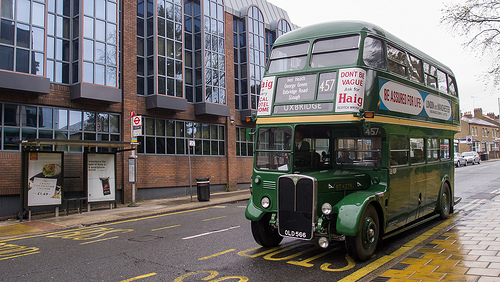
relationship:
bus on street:
[244, 20, 463, 263] [1, 160, 499, 282]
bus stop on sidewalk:
[18, 136, 142, 224] [0, 186, 253, 241]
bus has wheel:
[244, 20, 463, 263] [346, 205, 381, 262]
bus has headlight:
[244, 20, 463, 263] [321, 202, 331, 216]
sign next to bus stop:
[130, 113, 143, 138] [18, 136, 142, 224]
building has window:
[0, 0, 304, 214] [81, 60, 94, 82]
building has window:
[0, 0, 304, 214] [93, 61, 106, 86]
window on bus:
[311, 34, 361, 53] [244, 20, 463, 263]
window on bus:
[310, 50, 358, 68] [244, 20, 463, 263]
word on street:
[237, 240, 377, 272] [1, 160, 499, 282]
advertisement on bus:
[334, 67, 368, 114] [244, 20, 463, 263]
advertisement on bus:
[377, 74, 456, 124] [244, 20, 463, 263]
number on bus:
[318, 79, 336, 92] [244, 20, 463, 263]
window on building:
[81, 60, 94, 82] [0, 0, 304, 214]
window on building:
[93, 61, 106, 86] [0, 0, 304, 214]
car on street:
[463, 150, 481, 164] [1, 160, 499, 282]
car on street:
[453, 152, 468, 168] [1, 160, 499, 282]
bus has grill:
[244, 20, 463, 263] [277, 174, 316, 239]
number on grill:
[282, 228, 309, 240] [277, 174, 316, 239]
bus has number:
[244, 20, 463, 263] [318, 79, 336, 92]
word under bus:
[237, 240, 377, 272] [244, 20, 463, 263]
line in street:
[200, 246, 235, 260] [1, 160, 499, 282]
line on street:
[153, 223, 181, 232] [1, 160, 499, 282]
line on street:
[182, 223, 242, 240] [1, 160, 499, 282]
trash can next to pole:
[195, 176, 212, 202] [186, 135, 193, 201]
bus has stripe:
[244, 20, 463, 263] [255, 111, 462, 133]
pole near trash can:
[186, 135, 193, 201] [195, 176, 212, 202]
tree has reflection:
[437, 0, 499, 88] [96, 1, 259, 108]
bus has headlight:
[244, 20, 463, 263] [261, 197, 269, 207]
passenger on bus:
[336, 148, 353, 164] [244, 20, 463, 263]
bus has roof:
[244, 20, 463, 263] [271, 20, 456, 78]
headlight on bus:
[321, 202, 331, 216] [244, 20, 463, 263]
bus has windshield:
[244, 20, 463, 263] [331, 129, 381, 168]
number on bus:
[282, 228, 309, 240] [244, 20, 463, 263]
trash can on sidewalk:
[195, 176, 212, 202] [0, 186, 253, 241]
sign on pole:
[130, 113, 143, 138] [131, 110, 136, 205]